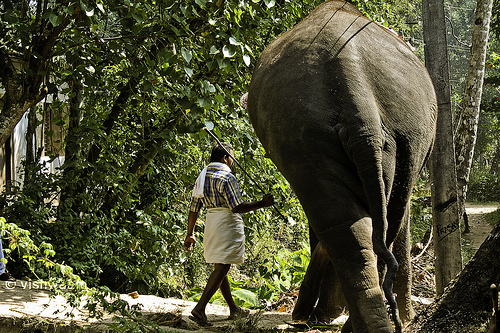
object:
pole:
[421, 0, 462, 295]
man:
[181, 142, 276, 326]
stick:
[203, 127, 289, 222]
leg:
[188, 263, 231, 327]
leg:
[220, 276, 250, 321]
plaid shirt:
[190, 162, 245, 213]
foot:
[341, 314, 394, 333]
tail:
[340, 136, 402, 332]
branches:
[31, 3, 193, 94]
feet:
[189, 318, 215, 326]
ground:
[0, 202, 500, 332]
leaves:
[0, 0, 327, 291]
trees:
[84, 0, 280, 229]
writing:
[436, 219, 459, 243]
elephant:
[240, 0, 439, 333]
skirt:
[203, 207, 248, 265]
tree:
[0, 0, 197, 150]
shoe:
[0, 269, 16, 281]